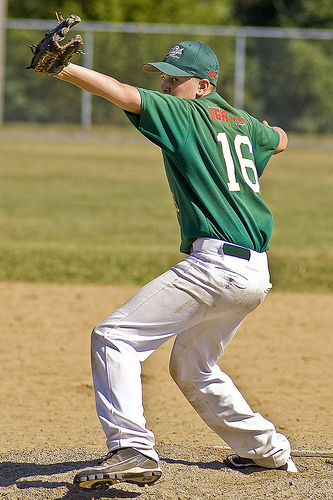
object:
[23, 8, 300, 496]
boy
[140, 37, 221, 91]
hat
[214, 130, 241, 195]
number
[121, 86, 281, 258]
shirt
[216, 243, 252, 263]
belt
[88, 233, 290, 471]
pants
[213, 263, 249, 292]
pocket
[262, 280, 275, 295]
pocket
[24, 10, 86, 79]
glove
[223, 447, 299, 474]
foot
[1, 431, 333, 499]
pitcher mound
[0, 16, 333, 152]
fence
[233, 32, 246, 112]
pole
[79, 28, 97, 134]
pole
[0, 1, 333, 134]
trees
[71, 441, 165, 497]
shoe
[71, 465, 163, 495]
sole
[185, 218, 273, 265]
waist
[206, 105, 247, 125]
sponsor name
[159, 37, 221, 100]
head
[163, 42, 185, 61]
logo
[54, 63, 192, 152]
arm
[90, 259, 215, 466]
leg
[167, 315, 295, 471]
leg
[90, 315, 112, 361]
knee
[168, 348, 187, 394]
knee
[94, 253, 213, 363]
thigh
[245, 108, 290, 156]
arm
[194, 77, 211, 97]
ear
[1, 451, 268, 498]
shadow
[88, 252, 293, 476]
dirt stains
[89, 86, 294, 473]
uniform